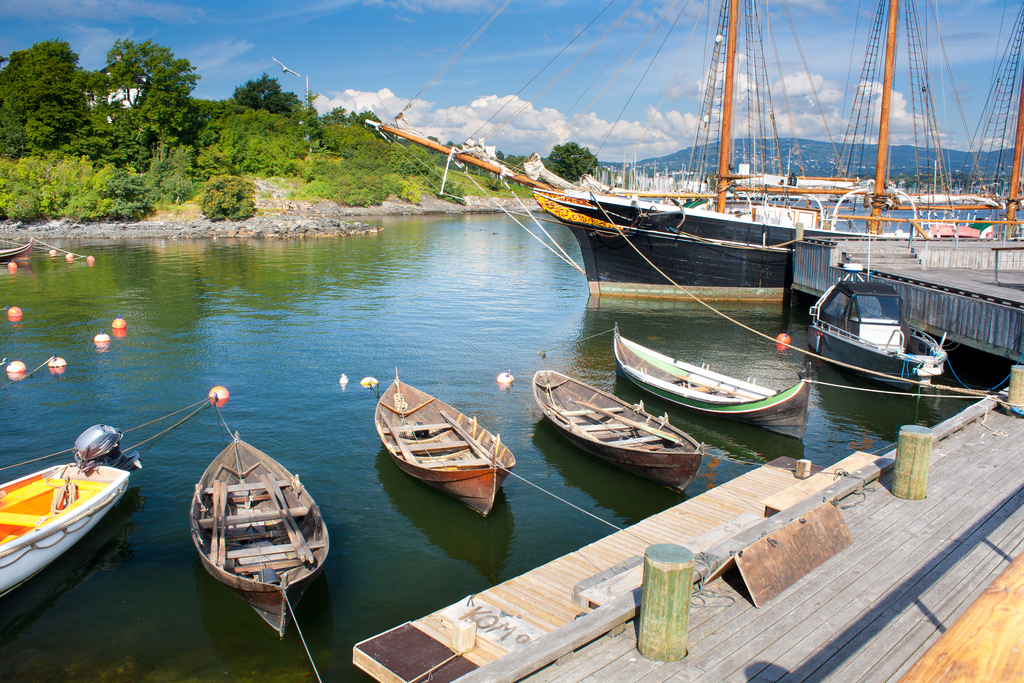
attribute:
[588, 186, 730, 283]
boat — dock